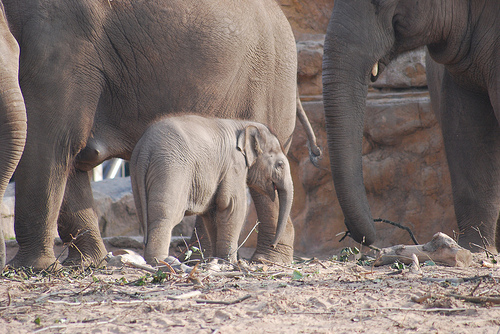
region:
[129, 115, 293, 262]
A small grey baby elephant.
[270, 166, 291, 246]
Baby elephant trunk.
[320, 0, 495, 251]
A dark grey large elephant.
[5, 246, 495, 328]
A brown ground with sticks all over.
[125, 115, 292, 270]
A light brown elephant that is a baby.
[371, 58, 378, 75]
A white elephant tusk.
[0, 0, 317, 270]
Very large lighter grey elephant.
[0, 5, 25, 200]
Only visible part of an elephants head and trunk.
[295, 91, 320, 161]
A light grey tail on a very large elephant.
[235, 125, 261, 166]
A baby elephants right ear.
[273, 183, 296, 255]
trunk of baby elephant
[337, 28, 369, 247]
trunk on adult elephant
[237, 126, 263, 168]
ear on young elephant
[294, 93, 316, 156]
tail on large elephant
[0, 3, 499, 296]
several elephants standing up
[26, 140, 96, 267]
front legs on large elephant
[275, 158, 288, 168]
eye on small elephant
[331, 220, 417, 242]
twig in elephant's trunk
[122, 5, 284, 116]
wrinkled skin on elephant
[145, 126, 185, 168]
behind on small elephant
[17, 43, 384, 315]
these are a herd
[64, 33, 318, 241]
this is an elephant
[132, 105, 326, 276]
the elephant is a baby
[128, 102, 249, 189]
the elephant is small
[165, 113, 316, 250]
the elephant is gray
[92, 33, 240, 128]
the elephant is large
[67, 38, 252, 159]
the skin is rough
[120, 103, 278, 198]
the elephant is fuzzy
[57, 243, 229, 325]
the ground is grass and dirt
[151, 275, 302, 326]
the ground is light brown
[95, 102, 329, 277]
this is an elephant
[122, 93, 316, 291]
this is a baby elephant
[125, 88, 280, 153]
hair on the elephant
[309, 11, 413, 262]
trunk of the elephant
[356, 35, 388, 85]
tusk on the elephant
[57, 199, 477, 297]
sticks on the ground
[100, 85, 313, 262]
the elephant is grey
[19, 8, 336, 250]
dirt on the elephant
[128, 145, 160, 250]
tail of the elephant